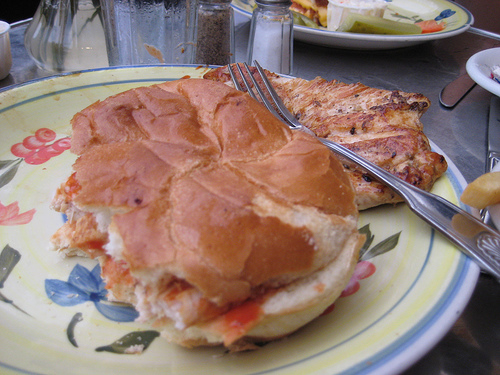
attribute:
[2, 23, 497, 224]
table — grey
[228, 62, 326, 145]
fork — silver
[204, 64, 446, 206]
meat — browned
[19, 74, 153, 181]
plate — blue, white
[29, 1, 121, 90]
vase — glass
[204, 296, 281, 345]
sauce — red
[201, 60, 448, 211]
chicken — brown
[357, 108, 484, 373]
edging — yellow, blue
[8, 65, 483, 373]
plate — round, yellow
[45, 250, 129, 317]
flower — blue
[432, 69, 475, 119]
knife — butter knife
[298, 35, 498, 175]
edge — shiny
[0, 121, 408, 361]
pattern — floral